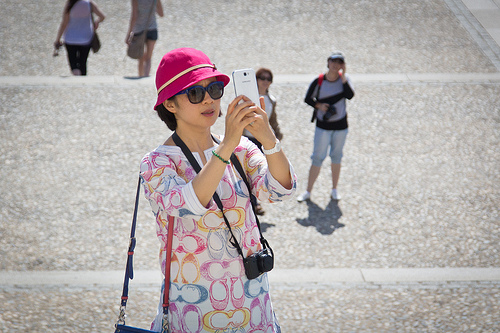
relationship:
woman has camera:
[140, 47, 296, 333] [243, 249, 274, 279]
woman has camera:
[140, 47, 296, 333] [231, 68, 262, 116]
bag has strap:
[114, 323, 161, 333] [122, 170, 176, 312]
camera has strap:
[243, 249, 274, 279] [171, 130, 270, 259]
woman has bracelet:
[140, 47, 296, 333] [211, 148, 231, 166]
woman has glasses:
[140, 47, 296, 333] [172, 80, 227, 105]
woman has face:
[140, 47, 296, 333] [163, 75, 221, 127]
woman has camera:
[140, 47, 296, 333] [232, 68, 263, 110]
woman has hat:
[140, 47, 296, 333] [152, 46, 230, 112]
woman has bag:
[140, 47, 296, 333] [114, 323, 161, 333]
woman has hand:
[140, 47, 296, 333] [223, 95, 259, 152]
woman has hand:
[140, 47, 296, 333] [236, 95, 273, 142]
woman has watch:
[140, 47, 296, 333] [262, 138, 283, 156]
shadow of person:
[294, 197, 347, 236] [296, 41, 362, 212]